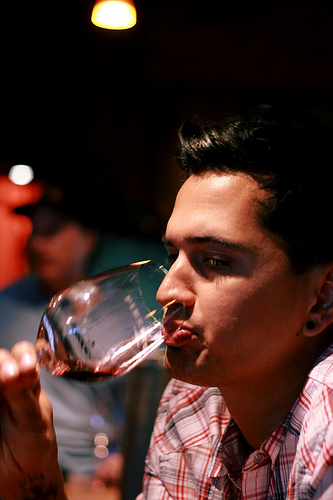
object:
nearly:
[33, 258, 182, 382]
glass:
[30, 254, 191, 385]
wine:
[33, 302, 118, 391]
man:
[134, 118, 329, 493]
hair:
[169, 98, 331, 280]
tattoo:
[16, 475, 64, 499]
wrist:
[8, 466, 66, 499]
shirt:
[134, 349, 330, 500]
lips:
[160, 320, 191, 334]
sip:
[149, 312, 198, 361]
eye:
[187, 239, 237, 295]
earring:
[299, 318, 320, 336]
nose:
[154, 252, 197, 310]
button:
[250, 452, 273, 469]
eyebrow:
[184, 230, 252, 259]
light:
[86, 1, 140, 37]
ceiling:
[6, 3, 331, 153]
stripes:
[311, 360, 331, 496]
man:
[0, 180, 168, 490]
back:
[4, 3, 329, 277]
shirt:
[6, 278, 151, 471]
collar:
[198, 419, 298, 498]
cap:
[19, 179, 93, 229]